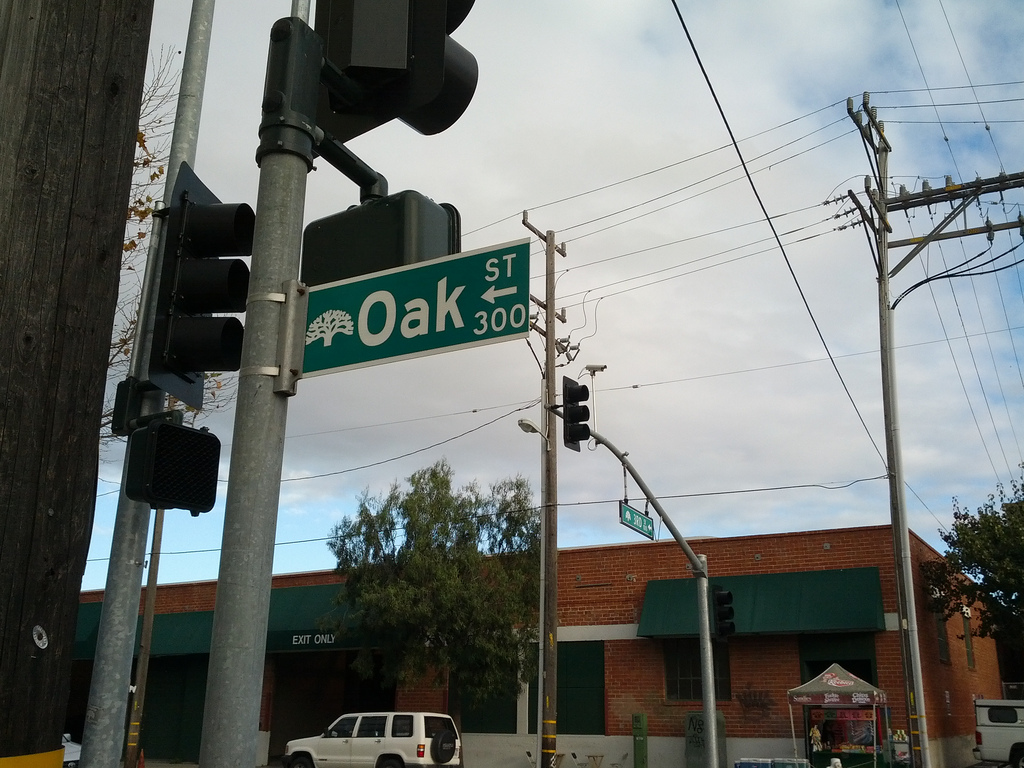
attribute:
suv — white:
[265, 675, 503, 765]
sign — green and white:
[242, 215, 576, 412]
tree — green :
[313, 460, 554, 732]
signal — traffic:
[118, 173, 276, 422]